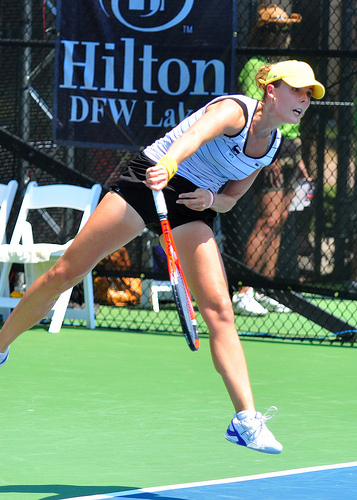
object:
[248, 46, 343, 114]
yellow cap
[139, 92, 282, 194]
striped tank top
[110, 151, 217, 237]
black shorts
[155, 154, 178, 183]
yellow band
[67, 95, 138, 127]
letters dfw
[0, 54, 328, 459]
lady jumping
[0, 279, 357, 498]
tennis court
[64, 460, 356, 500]
white baseline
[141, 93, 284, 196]
black striped shirt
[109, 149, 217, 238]
black shorts on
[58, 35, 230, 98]
hilton sign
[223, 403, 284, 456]
athletic sneakers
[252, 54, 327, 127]
wearing a hat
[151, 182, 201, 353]
hockey stick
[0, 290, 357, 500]
on the sidewalk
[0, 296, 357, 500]
spotless green lawn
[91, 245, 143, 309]
an orange object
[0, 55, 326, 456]
woman wearing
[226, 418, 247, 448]
blue design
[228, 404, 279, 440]
white shoelaces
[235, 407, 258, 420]
white sock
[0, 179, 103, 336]
folding chair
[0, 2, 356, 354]
black fence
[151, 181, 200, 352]
racquet is white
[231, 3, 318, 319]
person standing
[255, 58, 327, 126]
head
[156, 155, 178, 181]
wrist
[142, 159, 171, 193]
hand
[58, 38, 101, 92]
letter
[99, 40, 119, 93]
letter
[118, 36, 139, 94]
letter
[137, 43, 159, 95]
letter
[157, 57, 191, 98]
letter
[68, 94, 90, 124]
letter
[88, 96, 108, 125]
letter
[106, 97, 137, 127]
letter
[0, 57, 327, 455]
tennis player